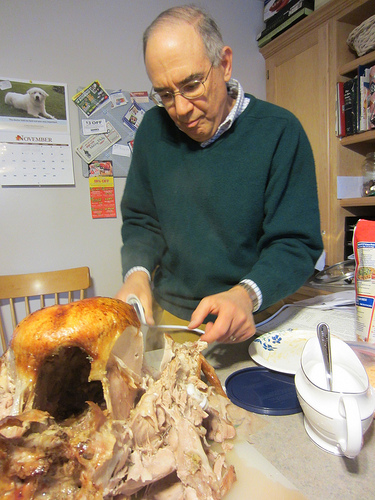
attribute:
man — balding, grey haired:
[113, 7, 323, 350]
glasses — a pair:
[144, 58, 217, 108]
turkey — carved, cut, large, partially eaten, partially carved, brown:
[5, 296, 233, 500]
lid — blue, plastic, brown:
[223, 362, 309, 417]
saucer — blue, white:
[247, 326, 318, 378]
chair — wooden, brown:
[0, 267, 93, 347]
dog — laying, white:
[5, 86, 59, 121]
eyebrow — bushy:
[179, 67, 207, 86]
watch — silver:
[235, 279, 259, 310]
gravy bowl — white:
[299, 335, 374, 462]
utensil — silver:
[310, 321, 338, 393]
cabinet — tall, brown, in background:
[259, 2, 374, 278]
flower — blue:
[262, 338, 277, 354]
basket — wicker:
[345, 12, 375, 56]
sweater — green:
[118, 94, 321, 323]